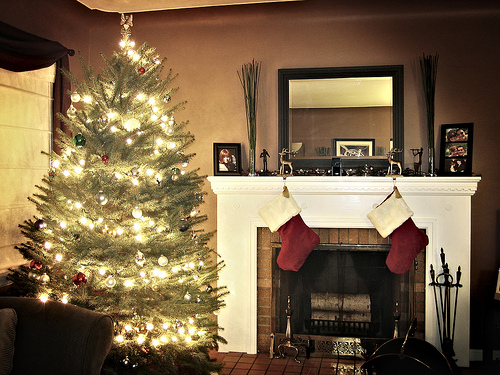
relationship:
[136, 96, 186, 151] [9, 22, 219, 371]
lights on tree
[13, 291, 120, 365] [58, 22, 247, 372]
couch next to tree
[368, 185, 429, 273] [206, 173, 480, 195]
stocking hung on mantle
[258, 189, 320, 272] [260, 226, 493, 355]
stocking hung on fireplace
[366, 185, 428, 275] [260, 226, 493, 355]
stocking hung on fireplace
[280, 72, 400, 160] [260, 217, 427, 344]
mirror hanging over fireplace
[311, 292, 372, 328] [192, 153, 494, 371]
logs in fireplace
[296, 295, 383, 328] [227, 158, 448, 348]
logs in fireplace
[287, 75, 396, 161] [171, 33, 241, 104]
mirror mounted to wall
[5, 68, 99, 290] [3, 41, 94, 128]
windws with brown drapes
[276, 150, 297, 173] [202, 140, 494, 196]
reindeer on mantle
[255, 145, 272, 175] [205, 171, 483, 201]
statue on mantle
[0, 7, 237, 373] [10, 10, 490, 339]
christmas tree in living room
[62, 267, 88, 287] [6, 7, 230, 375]
ornament on christmas tree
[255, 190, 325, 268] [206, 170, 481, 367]
stocking on fireplace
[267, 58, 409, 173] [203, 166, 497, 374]
framed mirror above fireplace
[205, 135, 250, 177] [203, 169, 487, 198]
photo sitting on mantel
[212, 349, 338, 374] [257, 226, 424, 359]
brick on fireplace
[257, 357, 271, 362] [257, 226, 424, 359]
brick on fireplace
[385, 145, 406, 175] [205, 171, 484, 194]
deer figurine on mantel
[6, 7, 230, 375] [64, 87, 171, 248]
christmas tree has lights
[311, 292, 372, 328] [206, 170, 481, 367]
logs in fireplace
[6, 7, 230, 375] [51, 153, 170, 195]
christmas tree with lights